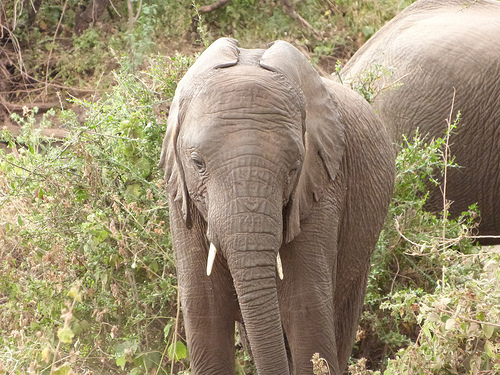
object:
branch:
[0, 121, 69, 151]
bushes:
[30, 47, 180, 375]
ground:
[0, 192, 494, 373]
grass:
[0, 3, 187, 375]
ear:
[255, 42, 345, 243]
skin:
[349, 93, 394, 220]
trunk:
[202, 161, 295, 374]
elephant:
[160, 37, 403, 374]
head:
[170, 35, 328, 374]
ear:
[158, 31, 238, 230]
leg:
[170, 216, 236, 373]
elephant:
[328, 2, 499, 246]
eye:
[189, 153, 204, 173]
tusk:
[204, 241, 216, 275]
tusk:
[275, 249, 284, 280]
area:
[0, 0, 499, 374]